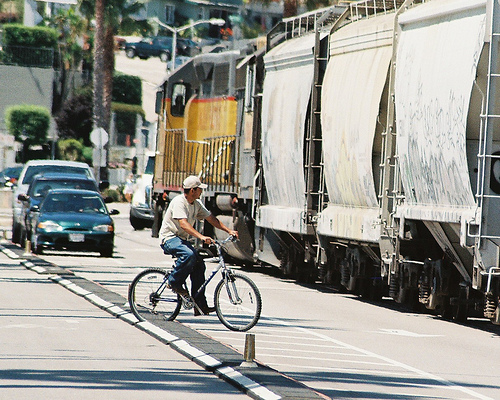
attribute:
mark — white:
[352, 336, 383, 363]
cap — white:
[179, 169, 211, 192]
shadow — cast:
[267, 343, 313, 398]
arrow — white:
[358, 316, 428, 351]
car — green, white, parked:
[31, 181, 117, 249]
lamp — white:
[173, 13, 226, 38]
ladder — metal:
[481, 140, 497, 251]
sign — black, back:
[77, 118, 108, 158]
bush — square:
[2, 105, 59, 137]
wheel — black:
[98, 245, 113, 261]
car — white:
[13, 159, 91, 172]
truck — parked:
[30, 159, 84, 168]